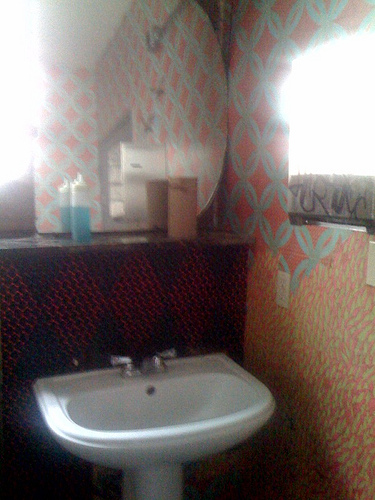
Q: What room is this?
A: Bathroom.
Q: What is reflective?
A: The mirror.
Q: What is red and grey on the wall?
A: Wallpaper.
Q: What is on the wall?
A: Red diamonds.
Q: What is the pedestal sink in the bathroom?
A: White.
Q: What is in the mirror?
A: Reflection of the wall.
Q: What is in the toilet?
A: Multicolored wall.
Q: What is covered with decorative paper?
A: Wall of the bathroom.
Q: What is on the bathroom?
A: The sink.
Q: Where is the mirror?
A: Above the sink.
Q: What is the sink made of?
A: Porcelain.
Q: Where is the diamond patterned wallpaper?
A: Above the sink.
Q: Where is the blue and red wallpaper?
A: On the right.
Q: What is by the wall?
A: Sink.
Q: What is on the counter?
A: Soap.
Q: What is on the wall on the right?
A: Mirror.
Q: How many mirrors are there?
A: Two.